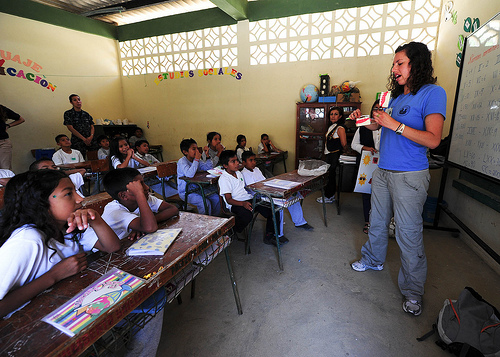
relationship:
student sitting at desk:
[1, 169, 123, 321] [0, 209, 251, 353]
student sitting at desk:
[85, 167, 180, 354] [0, 209, 251, 353]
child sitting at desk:
[217, 150, 283, 248] [245, 160, 330, 270]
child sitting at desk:
[240, 150, 314, 244] [245, 160, 330, 270]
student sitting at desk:
[176, 137, 220, 214] [179, 143, 288, 212]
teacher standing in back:
[0, 103, 26, 170] [0, 8, 133, 214]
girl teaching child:
[351, 41, 447, 315] [217, 150, 283, 248]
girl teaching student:
[351, 41, 447, 315] [1, 169, 123, 321]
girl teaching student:
[351, 41, 447, 315] [85, 164, 180, 256]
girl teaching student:
[351, 41, 447, 315] [175, 135, 218, 216]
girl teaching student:
[351, 41, 447, 315] [198, 131, 226, 168]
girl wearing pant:
[351, 41, 447, 315] [357, 167, 432, 302]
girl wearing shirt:
[351, 41, 447, 315] [375, 81, 448, 175]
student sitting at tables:
[101, 167, 180, 241] [0, 205, 250, 355]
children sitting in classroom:
[0, 126, 300, 310] [3, 2, 495, 354]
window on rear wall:
[249, 3, 439, 67] [115, 4, 456, 202]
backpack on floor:
[413, 286, 498, 356] [159, 184, 499, 356]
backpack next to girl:
[413, 286, 498, 356] [351, 41, 447, 315]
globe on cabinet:
[300, 84, 319, 103] [293, 101, 328, 156]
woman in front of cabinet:
[316, 105, 347, 203] [293, 100, 362, 192]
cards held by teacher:
[351, 86, 393, 133] [336, 55, 455, 271]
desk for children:
[245, 160, 330, 270] [0, 131, 315, 323]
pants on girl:
[359, 168, 431, 301] [351, 41, 447, 315]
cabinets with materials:
[290, 99, 369, 175] [301, 109, 324, 131]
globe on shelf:
[298, 82, 317, 101] [291, 102, 360, 193]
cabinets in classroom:
[295, 101, 363, 193] [3, 2, 495, 354]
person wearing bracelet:
[61, 90, 98, 153] [88, 128, 97, 138]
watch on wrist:
[397, 123, 406, 137] [396, 118, 408, 133]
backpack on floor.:
[413, 286, 498, 356] [233, 269, 323, 350]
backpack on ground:
[415, 286, 499, 356] [113, 184, 499, 355]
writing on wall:
[8, 49, 60, 98] [4, 12, 126, 173]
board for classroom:
[447, 13, 500, 184] [3, 2, 495, 354]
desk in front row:
[247, 164, 335, 269] [7, 160, 347, 355]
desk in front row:
[0, 209, 251, 353] [7, 160, 347, 355]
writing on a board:
[452, 47, 497, 172] [445, 6, 498, 192]